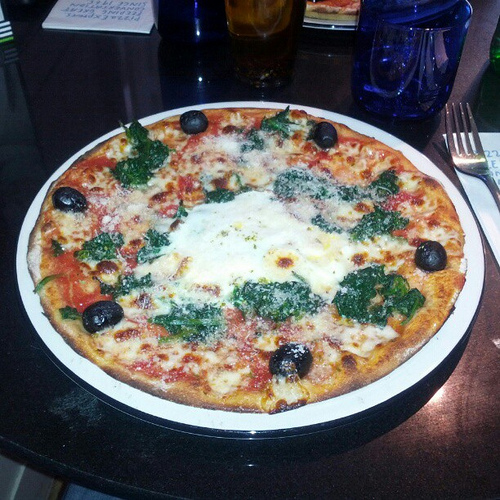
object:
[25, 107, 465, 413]
pizza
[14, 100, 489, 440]
plate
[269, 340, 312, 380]
olives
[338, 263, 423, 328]
vegetables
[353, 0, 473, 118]
cup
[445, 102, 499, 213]
fork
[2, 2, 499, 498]
table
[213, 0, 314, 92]
glass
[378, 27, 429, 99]
glasses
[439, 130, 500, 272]
napkin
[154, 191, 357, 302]
cheese